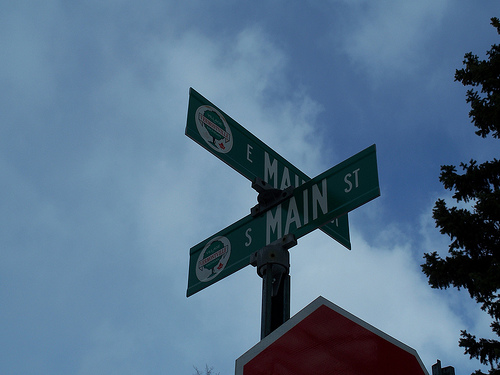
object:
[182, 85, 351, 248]
street sign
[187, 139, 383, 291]
street sign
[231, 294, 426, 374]
stop sign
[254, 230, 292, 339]
iron pole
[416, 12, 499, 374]
tree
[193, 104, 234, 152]
circular logo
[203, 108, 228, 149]
tree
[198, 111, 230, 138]
letters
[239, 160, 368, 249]
s main st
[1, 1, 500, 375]
cloud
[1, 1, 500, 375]
sky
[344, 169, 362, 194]
letters st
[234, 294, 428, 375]
border